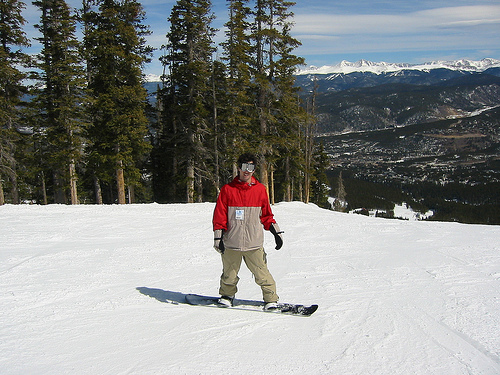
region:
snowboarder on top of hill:
[172, 112, 327, 332]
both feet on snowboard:
[176, 271, 321, 316]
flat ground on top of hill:
[105, 216, 396, 356]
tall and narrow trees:
[30, 6, 220, 191]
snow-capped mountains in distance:
[320, 46, 475, 78]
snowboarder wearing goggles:
[212, 141, 269, 186]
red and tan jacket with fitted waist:
[195, 160, 285, 257]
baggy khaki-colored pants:
[215, 245, 275, 305]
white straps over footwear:
[210, 285, 290, 310]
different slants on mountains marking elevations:
[336, 75, 486, 185]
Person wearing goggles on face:
[230, 147, 279, 186]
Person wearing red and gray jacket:
[203, 178, 287, 258]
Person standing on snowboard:
[182, 273, 301, 373]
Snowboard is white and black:
[175, 271, 375, 345]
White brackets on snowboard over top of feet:
[196, 283, 309, 338]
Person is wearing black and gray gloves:
[218, 205, 340, 300]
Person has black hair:
[220, 152, 285, 190]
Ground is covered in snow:
[66, 225, 301, 372]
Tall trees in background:
[32, 76, 338, 146]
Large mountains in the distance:
[321, 64, 420, 185]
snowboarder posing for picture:
[187, 151, 319, 318]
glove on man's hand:
[266, 220, 289, 252]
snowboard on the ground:
[180, 289, 325, 319]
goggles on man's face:
[235, 158, 260, 177]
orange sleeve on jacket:
[209, 185, 230, 237]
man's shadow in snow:
[130, 280, 187, 309]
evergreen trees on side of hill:
[266, 94, 334, 202]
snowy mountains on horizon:
[344, 56, 413, 78]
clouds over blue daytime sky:
[342, 7, 416, 53]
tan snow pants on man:
[213, 246, 280, 305]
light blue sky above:
[388, 54, 404, 59]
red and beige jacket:
[209, 174, 278, 249]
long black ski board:
[180, 291, 320, 318]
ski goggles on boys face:
[240, 160, 255, 170]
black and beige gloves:
[265, 223, 288, 251]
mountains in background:
[16, 56, 496, 224]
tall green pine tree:
[73, 0, 157, 201]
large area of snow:
[0, 201, 497, 373]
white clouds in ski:
[318, 14, 400, 31]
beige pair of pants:
[218, 248, 279, 304]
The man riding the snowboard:
[208, 148, 285, 321]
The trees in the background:
[2, 0, 325, 209]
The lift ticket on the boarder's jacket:
[231, 204, 248, 224]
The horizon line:
[0, 48, 497, 81]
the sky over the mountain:
[1, 1, 498, 65]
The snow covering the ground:
[1, 193, 496, 374]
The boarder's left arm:
[257, 185, 287, 246]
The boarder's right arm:
[206, 183, 231, 257]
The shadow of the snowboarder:
[134, 277, 221, 311]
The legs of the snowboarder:
[212, 251, 283, 303]